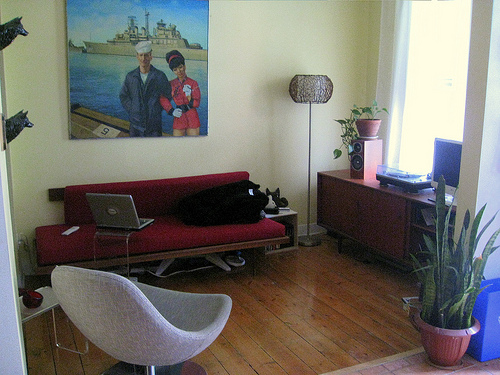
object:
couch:
[28, 167, 296, 284]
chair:
[50, 266, 236, 375]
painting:
[64, 0, 210, 142]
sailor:
[119, 39, 172, 137]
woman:
[159, 50, 201, 137]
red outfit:
[160, 75, 198, 129]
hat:
[133, 41, 154, 57]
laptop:
[84, 193, 153, 231]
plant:
[410, 174, 500, 330]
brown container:
[412, 314, 481, 365]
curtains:
[365, 1, 416, 170]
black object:
[180, 177, 272, 225]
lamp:
[288, 75, 334, 247]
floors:
[24, 236, 500, 375]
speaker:
[349, 138, 382, 178]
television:
[432, 136, 474, 196]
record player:
[375, 162, 436, 194]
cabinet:
[316, 164, 457, 274]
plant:
[328, 101, 391, 161]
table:
[19, 286, 104, 353]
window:
[390, 0, 476, 187]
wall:
[2, 0, 380, 273]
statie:
[0, 16, 31, 52]